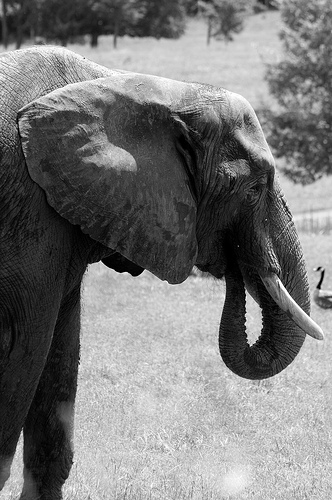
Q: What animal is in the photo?
A: Elephant.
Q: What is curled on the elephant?
A: Trunk.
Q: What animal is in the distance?
A: Geese.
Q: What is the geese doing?
A: Walking.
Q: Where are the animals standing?
A: On the field.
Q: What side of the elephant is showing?
A: Right.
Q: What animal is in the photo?
A: The elephant.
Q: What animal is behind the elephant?
A: A bird.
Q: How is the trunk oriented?
A: Curved.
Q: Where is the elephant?
A: On the grass.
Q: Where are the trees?
A: Behind the elephant.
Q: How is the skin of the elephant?
A: Wrinkled.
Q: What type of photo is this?
A: Black and white.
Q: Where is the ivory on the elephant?
A: The tusk.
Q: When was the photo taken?
A: During the daytime.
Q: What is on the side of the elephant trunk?
A: Tusk.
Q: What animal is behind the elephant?
A: Duck.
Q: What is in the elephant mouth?
A: Trunk.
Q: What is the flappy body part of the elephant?
A: Ear.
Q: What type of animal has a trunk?
A: Elephant.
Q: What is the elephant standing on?
A: Grass.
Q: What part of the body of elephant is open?
A: Eye.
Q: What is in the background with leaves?
A: Trees.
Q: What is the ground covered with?
A: Green.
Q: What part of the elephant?
A: Ears.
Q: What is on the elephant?
A: Mud.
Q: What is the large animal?
A: Elephant.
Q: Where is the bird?
A: Behind elephant.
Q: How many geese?
A: One.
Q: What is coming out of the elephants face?
A: Tusk.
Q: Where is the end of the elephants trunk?
A: In his mouth.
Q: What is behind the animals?
A: Trees.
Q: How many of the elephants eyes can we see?
A: One.